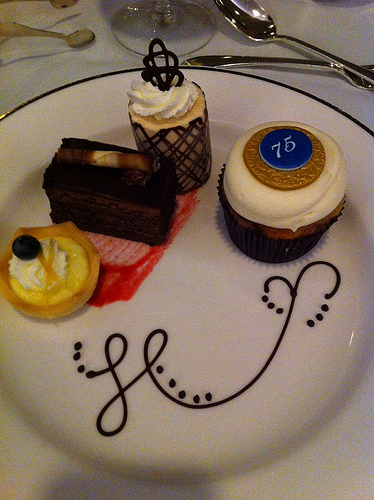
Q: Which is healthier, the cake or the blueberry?
A: The blueberry is healthier than the cake.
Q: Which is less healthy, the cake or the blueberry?
A: The cake is less healthy than the blueberry.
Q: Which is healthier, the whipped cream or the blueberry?
A: The blueberry is healthier than the whipped cream.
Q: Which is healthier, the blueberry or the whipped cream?
A: The blueberry is healthier than the whipped cream.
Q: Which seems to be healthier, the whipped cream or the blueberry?
A: The blueberry is healthier than the whipped cream.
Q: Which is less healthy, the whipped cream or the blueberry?
A: The whipped cream is less healthy than the blueberry.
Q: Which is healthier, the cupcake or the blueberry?
A: The blueberry is healthier than the cupcake.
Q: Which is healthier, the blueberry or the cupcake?
A: The blueberry is healthier than the cupcake.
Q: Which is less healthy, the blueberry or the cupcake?
A: The cupcake is less healthy than the blueberry.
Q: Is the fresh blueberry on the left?
A: Yes, the blueberry is on the left of the image.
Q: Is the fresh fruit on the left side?
A: Yes, the blueberry is on the left of the image.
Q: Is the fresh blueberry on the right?
A: No, the blueberry is on the left of the image.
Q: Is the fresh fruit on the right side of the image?
A: No, the blueberry is on the left of the image.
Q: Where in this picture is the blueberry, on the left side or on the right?
A: The blueberry is on the left of the image.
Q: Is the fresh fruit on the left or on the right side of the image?
A: The blueberry is on the left of the image.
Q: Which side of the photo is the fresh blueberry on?
A: The blueberry is on the left of the image.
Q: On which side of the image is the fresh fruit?
A: The blueberry is on the left of the image.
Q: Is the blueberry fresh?
A: Yes, the blueberry is fresh.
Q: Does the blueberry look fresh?
A: Yes, the blueberry is fresh.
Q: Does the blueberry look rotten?
A: No, the blueberry is fresh.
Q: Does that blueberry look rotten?
A: No, the blueberry is fresh.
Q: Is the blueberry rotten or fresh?
A: The blueberry is fresh.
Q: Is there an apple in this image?
A: No, there are no apples.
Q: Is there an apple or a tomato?
A: No, there are no apples or tomatoes.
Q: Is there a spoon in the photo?
A: Yes, there is a spoon.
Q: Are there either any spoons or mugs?
A: Yes, there is a spoon.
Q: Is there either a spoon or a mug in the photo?
A: Yes, there is a spoon.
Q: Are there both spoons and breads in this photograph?
A: No, there is a spoon but no breads.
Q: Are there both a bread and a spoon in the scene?
A: No, there is a spoon but no breads.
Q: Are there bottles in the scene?
A: No, there are no bottles.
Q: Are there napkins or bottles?
A: No, there are no bottles or napkins.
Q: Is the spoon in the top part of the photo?
A: Yes, the spoon is in the top of the image.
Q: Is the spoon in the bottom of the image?
A: No, the spoon is in the top of the image.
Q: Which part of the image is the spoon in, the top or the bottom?
A: The spoon is in the top of the image.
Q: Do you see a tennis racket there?
A: No, there are no rackets.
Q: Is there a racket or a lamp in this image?
A: No, there are no rackets or lamps.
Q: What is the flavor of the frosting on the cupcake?
A: This is a vanilla frosting.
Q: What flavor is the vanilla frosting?
A: This is a vanilla frosting.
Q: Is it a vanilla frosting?
A: Yes, this is a vanilla frosting.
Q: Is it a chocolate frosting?
A: No, this is a vanilla frosting.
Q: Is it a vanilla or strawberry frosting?
A: This is a vanilla frosting.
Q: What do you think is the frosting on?
A: The frosting is on the cupcake.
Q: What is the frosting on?
A: The frosting is on the cupcake.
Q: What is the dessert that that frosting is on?
A: The dessert is a cupcake.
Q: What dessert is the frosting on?
A: The frosting is on the cupcake.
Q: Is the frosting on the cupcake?
A: Yes, the frosting is on the cupcake.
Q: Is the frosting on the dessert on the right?
A: Yes, the frosting is on the cupcake.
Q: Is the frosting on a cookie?
A: No, the frosting is on the cupcake.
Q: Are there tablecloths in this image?
A: Yes, there is a tablecloth.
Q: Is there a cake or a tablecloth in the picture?
A: Yes, there is a tablecloth.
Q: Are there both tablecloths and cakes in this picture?
A: Yes, there are both a tablecloth and a cake.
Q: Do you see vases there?
A: No, there are no vases.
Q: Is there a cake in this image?
A: Yes, there is a cake.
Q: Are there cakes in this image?
A: Yes, there is a cake.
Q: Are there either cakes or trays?
A: Yes, there is a cake.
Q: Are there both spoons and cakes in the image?
A: Yes, there are both a cake and a spoon.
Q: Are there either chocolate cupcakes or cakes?
A: Yes, there is a chocolate cake.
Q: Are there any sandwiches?
A: No, there are no sandwiches.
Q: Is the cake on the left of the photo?
A: Yes, the cake is on the left of the image.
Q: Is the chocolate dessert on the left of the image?
A: Yes, the cake is on the left of the image.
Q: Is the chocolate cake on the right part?
A: No, the cake is on the left of the image.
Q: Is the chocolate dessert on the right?
A: No, the cake is on the left of the image.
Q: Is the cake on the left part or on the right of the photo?
A: The cake is on the left of the image.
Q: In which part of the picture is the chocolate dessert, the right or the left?
A: The cake is on the left of the image.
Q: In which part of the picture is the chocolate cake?
A: The cake is on the left of the image.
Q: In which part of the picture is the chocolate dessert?
A: The cake is on the left of the image.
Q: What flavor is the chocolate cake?
A: This is a chocolate cake.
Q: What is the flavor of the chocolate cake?
A: This is a chocolate cake.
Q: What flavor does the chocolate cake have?
A: This is a chocolate cake.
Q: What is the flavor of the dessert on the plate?
A: This is a chocolate cake.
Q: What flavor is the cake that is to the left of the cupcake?
A: This is a chocolate cake.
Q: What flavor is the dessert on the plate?
A: This is a chocolate cake.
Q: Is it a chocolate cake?
A: Yes, this is a chocolate cake.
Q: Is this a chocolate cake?
A: Yes, this is a chocolate cake.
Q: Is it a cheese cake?
A: No, this is a chocolate cake.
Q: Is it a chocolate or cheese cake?
A: This is a chocolate cake.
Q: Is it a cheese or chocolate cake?
A: This is a chocolate cake.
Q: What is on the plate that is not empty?
A: The cake is on the plate.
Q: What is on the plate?
A: The cake is on the plate.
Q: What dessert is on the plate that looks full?
A: The dessert is a cake.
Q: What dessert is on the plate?
A: The dessert is a cake.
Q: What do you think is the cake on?
A: The cake is on the plate.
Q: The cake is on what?
A: The cake is on the plate.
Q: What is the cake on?
A: The cake is on the plate.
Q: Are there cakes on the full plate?
A: Yes, there is a cake on the plate.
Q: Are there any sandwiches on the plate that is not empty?
A: No, there is a cake on the plate.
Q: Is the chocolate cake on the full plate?
A: Yes, the cake is on the plate.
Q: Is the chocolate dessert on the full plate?
A: Yes, the cake is on the plate.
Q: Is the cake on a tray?
A: No, the cake is on the plate.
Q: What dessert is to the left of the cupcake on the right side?
A: The dessert is a cake.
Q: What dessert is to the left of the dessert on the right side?
A: The dessert is a cake.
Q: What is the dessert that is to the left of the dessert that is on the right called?
A: The dessert is a cake.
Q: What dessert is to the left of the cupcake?
A: The dessert is a cake.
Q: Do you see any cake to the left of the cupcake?
A: Yes, there is a cake to the left of the cupcake.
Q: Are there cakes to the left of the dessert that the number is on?
A: Yes, there is a cake to the left of the cupcake.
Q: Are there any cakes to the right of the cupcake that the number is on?
A: No, the cake is to the left of the cupcake.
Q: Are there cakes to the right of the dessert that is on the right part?
A: No, the cake is to the left of the cupcake.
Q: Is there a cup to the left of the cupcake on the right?
A: No, there is a cake to the left of the cupcake.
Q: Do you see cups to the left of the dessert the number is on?
A: No, there is a cake to the left of the cupcake.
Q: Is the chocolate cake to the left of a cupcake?
A: Yes, the cake is to the left of a cupcake.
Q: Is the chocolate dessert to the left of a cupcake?
A: Yes, the cake is to the left of a cupcake.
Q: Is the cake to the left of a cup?
A: No, the cake is to the left of a cupcake.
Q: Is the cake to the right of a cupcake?
A: No, the cake is to the left of a cupcake.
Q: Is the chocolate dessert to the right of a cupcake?
A: No, the cake is to the left of a cupcake.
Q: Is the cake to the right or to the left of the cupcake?
A: The cake is to the left of the cupcake.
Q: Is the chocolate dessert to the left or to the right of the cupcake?
A: The cake is to the left of the cupcake.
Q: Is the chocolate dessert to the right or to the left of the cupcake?
A: The cake is to the left of the cupcake.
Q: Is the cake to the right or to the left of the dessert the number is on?
A: The cake is to the left of the cupcake.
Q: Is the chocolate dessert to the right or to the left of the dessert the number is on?
A: The cake is to the left of the cupcake.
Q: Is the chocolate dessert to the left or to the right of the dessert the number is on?
A: The cake is to the left of the cupcake.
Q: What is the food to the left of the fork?
A: The food is a pastry.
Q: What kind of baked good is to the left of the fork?
A: The food is a pastry.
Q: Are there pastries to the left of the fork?
A: Yes, there is a pastry to the left of the fork.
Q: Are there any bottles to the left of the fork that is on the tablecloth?
A: No, there is a pastry to the left of the fork.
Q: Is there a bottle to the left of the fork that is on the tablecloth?
A: No, there is a pastry to the left of the fork.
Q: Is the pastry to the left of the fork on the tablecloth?
A: Yes, the pastry is to the left of the fork.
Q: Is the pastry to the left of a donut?
A: No, the pastry is to the left of the fork.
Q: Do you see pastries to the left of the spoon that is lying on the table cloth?
A: Yes, there is a pastry to the left of the spoon.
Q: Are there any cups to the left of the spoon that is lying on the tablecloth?
A: No, there is a pastry to the left of the spoon.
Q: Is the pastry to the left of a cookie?
A: No, the pastry is to the left of a spoon.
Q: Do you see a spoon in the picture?
A: Yes, there is a spoon.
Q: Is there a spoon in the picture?
A: Yes, there is a spoon.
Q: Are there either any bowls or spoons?
A: Yes, there is a spoon.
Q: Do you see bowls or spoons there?
A: Yes, there is a spoon.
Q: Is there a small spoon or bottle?
A: Yes, there is a small spoon.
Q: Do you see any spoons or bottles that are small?
A: Yes, the spoon is small.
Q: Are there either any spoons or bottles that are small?
A: Yes, the spoon is small.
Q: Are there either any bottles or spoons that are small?
A: Yes, the spoon is small.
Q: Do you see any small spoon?
A: Yes, there is a small spoon.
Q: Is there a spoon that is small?
A: Yes, there is a spoon that is small.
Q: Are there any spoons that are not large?
A: Yes, there is a small spoon.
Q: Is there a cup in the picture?
A: No, there are no cups.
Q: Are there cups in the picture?
A: No, there are no cups.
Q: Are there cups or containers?
A: No, there are no cups or containers.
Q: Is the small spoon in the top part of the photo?
A: Yes, the spoon is in the top of the image.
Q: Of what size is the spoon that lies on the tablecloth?
A: The spoon is small.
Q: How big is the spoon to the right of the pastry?
A: The spoon is small.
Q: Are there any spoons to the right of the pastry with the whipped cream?
A: Yes, there is a spoon to the right of the pastry.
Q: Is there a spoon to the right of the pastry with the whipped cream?
A: Yes, there is a spoon to the right of the pastry.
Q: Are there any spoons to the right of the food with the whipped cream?
A: Yes, there is a spoon to the right of the pastry.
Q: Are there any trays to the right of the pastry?
A: No, there is a spoon to the right of the pastry.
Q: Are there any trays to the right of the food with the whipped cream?
A: No, there is a spoon to the right of the pastry.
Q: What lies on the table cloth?
A: The spoon lies on the table cloth.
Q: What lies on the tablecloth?
A: The spoon lies on the table cloth.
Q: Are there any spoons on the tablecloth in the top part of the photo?
A: Yes, there is a spoon on the table cloth.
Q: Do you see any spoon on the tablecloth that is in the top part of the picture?
A: Yes, there is a spoon on the table cloth.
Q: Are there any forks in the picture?
A: Yes, there is a fork.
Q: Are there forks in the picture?
A: Yes, there is a fork.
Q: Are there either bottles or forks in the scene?
A: Yes, there is a fork.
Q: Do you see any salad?
A: No, there is no salad.